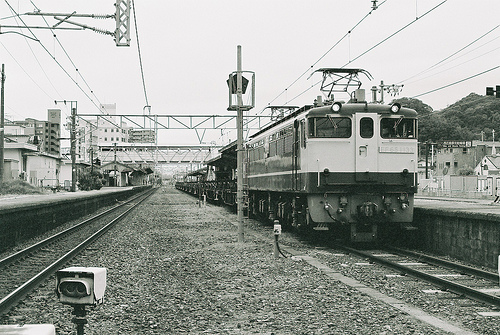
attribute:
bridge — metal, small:
[73, 114, 286, 165]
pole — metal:
[227, 44, 256, 241]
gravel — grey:
[154, 196, 281, 333]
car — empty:
[163, 148, 251, 219]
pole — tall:
[227, 111, 254, 248]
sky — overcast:
[0, 1, 498, 147]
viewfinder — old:
[50, 258, 112, 332]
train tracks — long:
[44, 178, 161, 296]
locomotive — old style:
[176, 103, 413, 246]